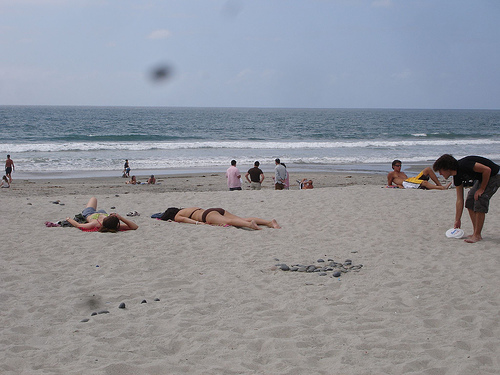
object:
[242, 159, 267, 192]
person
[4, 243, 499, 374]
beach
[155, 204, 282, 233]
lady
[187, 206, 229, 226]
bikini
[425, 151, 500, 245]
guy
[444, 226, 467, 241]
frisbee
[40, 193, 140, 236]
person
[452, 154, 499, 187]
shirt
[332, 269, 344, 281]
rock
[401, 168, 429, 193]
shorts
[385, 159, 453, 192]
guy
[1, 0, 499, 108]
sky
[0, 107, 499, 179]
water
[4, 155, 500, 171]
wave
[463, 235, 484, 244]
foot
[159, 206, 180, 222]
head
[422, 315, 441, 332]
footprint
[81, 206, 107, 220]
shorts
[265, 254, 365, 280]
pile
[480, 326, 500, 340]
footprint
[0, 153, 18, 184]
man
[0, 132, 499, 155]
wave